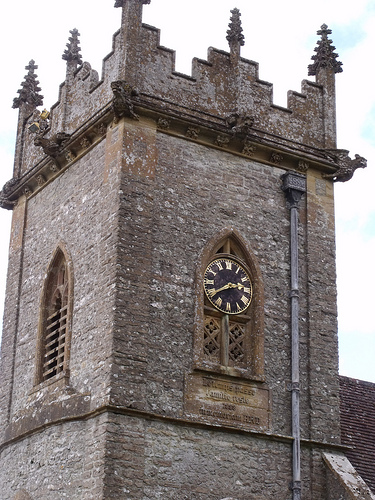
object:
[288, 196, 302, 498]
pipe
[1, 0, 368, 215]
top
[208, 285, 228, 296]
hand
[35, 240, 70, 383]
window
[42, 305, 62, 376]
bars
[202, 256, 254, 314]
clock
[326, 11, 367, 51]
sky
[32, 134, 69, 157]
gargoyle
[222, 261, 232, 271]
number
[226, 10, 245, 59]
statue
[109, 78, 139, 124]
decorative piece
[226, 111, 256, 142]
decorative piece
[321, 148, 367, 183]
decorative piece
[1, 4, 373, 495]
tower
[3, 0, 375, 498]
building